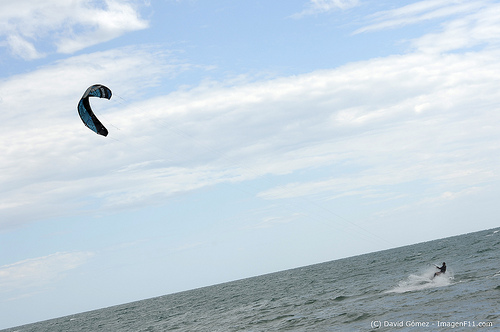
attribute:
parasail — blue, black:
[73, 79, 120, 145]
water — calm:
[0, 226, 499, 331]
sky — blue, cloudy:
[3, 2, 499, 227]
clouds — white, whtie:
[229, 74, 447, 194]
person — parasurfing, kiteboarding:
[431, 260, 449, 280]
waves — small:
[254, 294, 366, 310]